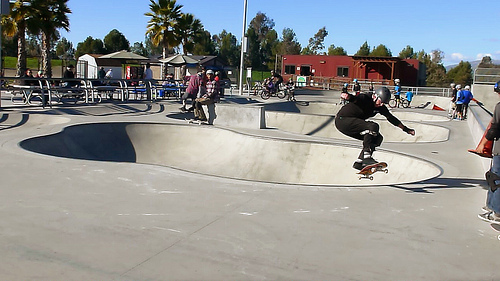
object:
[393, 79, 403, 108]
kid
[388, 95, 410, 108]
bicycle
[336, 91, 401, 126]
black shirt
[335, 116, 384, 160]
jeans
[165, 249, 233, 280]
pavement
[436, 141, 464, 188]
pavement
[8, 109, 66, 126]
pavement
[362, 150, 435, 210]
ground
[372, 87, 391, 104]
helmet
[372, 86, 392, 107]
head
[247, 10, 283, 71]
trees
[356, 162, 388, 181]
skateboard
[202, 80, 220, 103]
shirt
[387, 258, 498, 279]
pavement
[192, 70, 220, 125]
people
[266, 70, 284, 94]
guy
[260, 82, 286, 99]
bicycle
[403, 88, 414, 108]
boy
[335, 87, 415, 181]
boy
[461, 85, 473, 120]
boy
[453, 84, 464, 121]
boy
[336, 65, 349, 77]
window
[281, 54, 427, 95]
building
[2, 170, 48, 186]
pavement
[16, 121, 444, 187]
ramp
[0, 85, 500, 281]
skate park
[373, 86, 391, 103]
head gear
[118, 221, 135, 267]
pavement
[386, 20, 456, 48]
clouds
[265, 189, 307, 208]
pavement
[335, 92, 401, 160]
clothes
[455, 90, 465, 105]
top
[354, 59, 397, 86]
porch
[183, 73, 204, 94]
shirt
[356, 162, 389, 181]
bottom